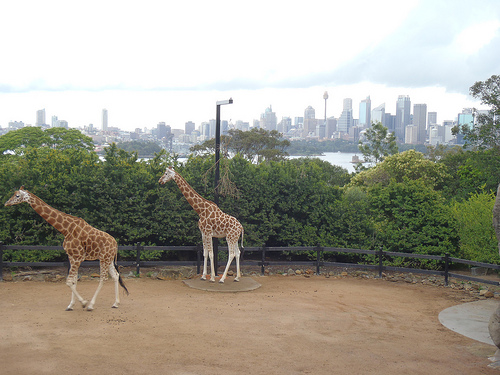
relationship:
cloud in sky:
[219, 19, 477, 100] [253, 22, 469, 103]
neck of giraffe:
[176, 167, 207, 211] [152, 162, 254, 289]